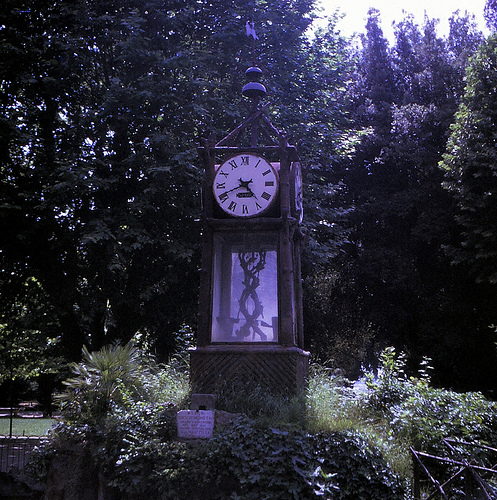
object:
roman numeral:
[226, 199, 239, 213]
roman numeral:
[259, 189, 271, 200]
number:
[259, 168, 273, 180]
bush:
[105, 402, 419, 499]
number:
[216, 167, 232, 181]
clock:
[210, 151, 279, 222]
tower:
[186, 60, 314, 414]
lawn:
[0, 415, 51, 436]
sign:
[174, 408, 218, 440]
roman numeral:
[238, 202, 251, 217]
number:
[251, 157, 261, 171]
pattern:
[227, 244, 271, 343]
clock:
[290, 160, 303, 222]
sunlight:
[292, 0, 493, 63]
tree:
[0, 0, 496, 419]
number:
[261, 180, 276, 188]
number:
[238, 152, 252, 167]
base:
[184, 345, 315, 422]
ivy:
[96, 411, 413, 498]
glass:
[209, 249, 280, 344]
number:
[215, 191, 230, 206]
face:
[212, 153, 279, 218]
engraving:
[175, 407, 216, 441]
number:
[253, 201, 264, 212]